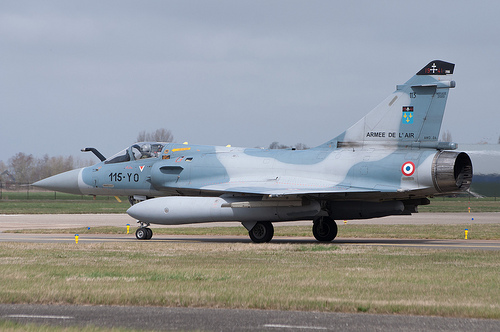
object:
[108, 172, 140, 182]
115-yo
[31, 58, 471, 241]
plane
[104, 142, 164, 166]
cockpit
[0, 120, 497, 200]
trees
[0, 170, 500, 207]
fence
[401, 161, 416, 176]
emblem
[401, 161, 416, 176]
paint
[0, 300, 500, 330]
paved road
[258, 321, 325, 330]
white line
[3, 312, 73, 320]
white line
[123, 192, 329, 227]
missle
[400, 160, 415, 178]
logo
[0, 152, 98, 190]
trees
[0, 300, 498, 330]
runway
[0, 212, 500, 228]
runway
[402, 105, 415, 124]
logo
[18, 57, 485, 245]
blue jet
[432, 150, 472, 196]
jet exhaust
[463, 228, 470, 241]
marker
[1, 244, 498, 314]
grass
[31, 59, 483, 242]
jet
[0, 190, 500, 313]
field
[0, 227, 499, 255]
runway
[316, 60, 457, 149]
tail